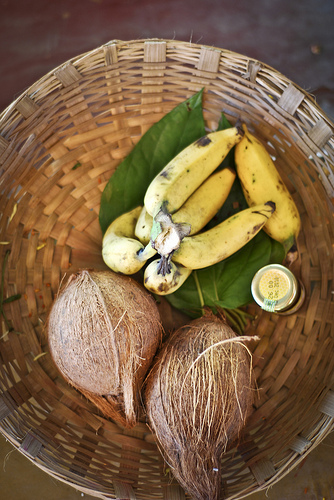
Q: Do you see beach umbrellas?
A: No, there are no beach umbrellas.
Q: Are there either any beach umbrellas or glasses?
A: No, there are no beach umbrellas or glasses.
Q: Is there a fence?
A: No, there are no fences.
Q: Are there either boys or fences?
A: No, there are no fences or boys.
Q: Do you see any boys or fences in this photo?
A: No, there are no fences or boys.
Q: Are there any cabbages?
A: No, there are no cabbages.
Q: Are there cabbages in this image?
A: No, there are no cabbages.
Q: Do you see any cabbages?
A: No, there are no cabbages.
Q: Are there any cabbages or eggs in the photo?
A: No, there are no cabbages or eggs.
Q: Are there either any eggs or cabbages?
A: No, there are no cabbages or eggs.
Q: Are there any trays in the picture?
A: No, there are no trays.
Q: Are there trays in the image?
A: No, there are no trays.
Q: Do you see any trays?
A: No, there are no trays.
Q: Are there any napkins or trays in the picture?
A: No, there are no trays or napkins.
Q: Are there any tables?
A: Yes, there is a table.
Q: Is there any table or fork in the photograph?
A: Yes, there is a table.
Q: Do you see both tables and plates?
A: No, there is a table but no plates.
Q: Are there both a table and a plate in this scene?
A: No, there is a table but no plates.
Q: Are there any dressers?
A: No, there are no dressers.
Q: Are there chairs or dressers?
A: No, there are no dressers or chairs.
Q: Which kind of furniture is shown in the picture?
A: The furniture is a table.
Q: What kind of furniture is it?
A: The piece of furniture is a table.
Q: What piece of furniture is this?
A: This is a table.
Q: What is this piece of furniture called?
A: This is a table.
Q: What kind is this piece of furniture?
A: This is a table.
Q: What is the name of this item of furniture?
A: This is a table.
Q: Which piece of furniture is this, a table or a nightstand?
A: This is a table.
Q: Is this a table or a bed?
A: This is a table.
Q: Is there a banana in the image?
A: Yes, there is a banana.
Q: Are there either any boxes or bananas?
A: Yes, there is a banana.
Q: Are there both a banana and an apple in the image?
A: No, there is a banana but no apples.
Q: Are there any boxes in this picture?
A: No, there are no boxes.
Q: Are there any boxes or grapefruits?
A: No, there are no boxes or grapefruits.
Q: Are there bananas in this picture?
A: Yes, there are bananas.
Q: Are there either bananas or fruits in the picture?
A: Yes, there are bananas.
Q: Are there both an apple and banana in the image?
A: No, there are bananas but no apples.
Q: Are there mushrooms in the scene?
A: No, there are no mushrooms.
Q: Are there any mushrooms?
A: No, there are no mushrooms.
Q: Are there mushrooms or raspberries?
A: No, there are no mushrooms or raspberries.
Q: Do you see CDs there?
A: No, there are no cds.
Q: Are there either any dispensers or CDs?
A: No, there are no CDs or dispensers.